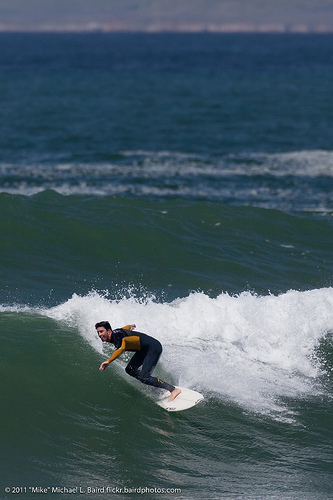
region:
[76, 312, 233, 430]
man surfing a wave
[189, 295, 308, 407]
wave breaking over the sea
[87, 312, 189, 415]
man wearing black wet suit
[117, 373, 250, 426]
man standing on white surf board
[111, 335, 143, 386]
orange sides to wet suit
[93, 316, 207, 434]
man with black hair surfing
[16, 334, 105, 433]
inside of a wave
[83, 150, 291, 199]
waves in the background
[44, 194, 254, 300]
second wave breaking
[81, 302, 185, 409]
a surfer stand on a surfboard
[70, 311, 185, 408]
surfer wears black and brown suit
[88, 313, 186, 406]
surfer is smiling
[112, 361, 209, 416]
surfboard is white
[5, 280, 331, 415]
surfer in a wave that roll in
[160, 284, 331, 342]
part of a wave that is splashing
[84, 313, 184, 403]
surfer is bend forward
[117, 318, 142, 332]
right hand of surfer is extended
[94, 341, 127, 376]
left arm of surfer is extended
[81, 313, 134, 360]
surfer has black hair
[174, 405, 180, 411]
THE SURFBOARD IS WHITE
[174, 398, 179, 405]
THE SURFBOARD IS WHITE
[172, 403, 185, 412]
THE SURFBOARD IS WHITE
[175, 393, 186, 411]
THE SURFBOARD IS WHITE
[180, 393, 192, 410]
THE SURFBOARD IS WHITE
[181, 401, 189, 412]
THE SURFBOARD IS WHITE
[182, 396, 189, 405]
THE SURFBOARD IS WHITE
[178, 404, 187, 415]
THE SURFBOARD IS WHITE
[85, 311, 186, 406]
a happy surfer in the ocean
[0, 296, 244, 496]
photo of a surfer was taken on 2011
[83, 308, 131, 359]
surfer has short hair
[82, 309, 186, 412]
surfer is bare feet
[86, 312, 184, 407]
the body of surfer in inclined forward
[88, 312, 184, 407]
man is crouching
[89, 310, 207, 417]
surfer wears a black and brown wetsuit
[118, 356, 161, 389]
two knees are bend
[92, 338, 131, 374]
a left hand is extended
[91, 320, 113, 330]
Hair is short and brown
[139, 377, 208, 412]
Surfboard is white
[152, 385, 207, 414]
Surfboard is half way out of the wave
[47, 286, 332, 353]
Foam of water is white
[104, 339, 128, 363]
Sleeve of wetsuit is camel brown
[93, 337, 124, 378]
Left arm is extended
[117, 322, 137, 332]
Right arm is extended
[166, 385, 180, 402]
Foot on surfboard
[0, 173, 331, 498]
Water is green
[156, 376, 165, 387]
Logo on leg of wetsuit